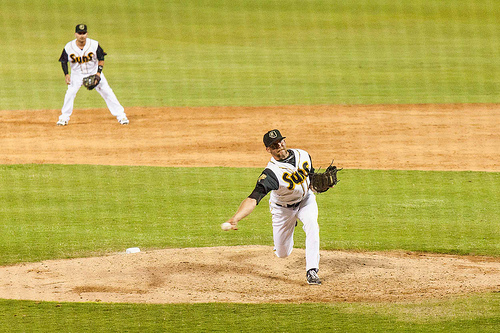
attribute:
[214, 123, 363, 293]
pitcher — determined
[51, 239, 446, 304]
mound — clean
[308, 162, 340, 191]
blak glove — black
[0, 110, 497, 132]
dirt — clean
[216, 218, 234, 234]
ball — baseball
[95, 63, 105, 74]
band — black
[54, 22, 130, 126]
player — alert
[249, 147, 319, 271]
uniform — white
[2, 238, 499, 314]
mound — round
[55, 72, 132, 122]
pants — white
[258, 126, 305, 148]
hat — black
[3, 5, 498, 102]
grass — alot, short, green, yellow, low cut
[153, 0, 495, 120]
grass — green and yellow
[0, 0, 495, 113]
grass — green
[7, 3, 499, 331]
grass — green, short, yellow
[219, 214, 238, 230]
baseball — white, round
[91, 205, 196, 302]
box — white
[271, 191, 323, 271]
pants — white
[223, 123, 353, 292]
player — baseball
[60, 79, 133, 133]
legs — separated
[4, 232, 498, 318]
mound — pitcher's